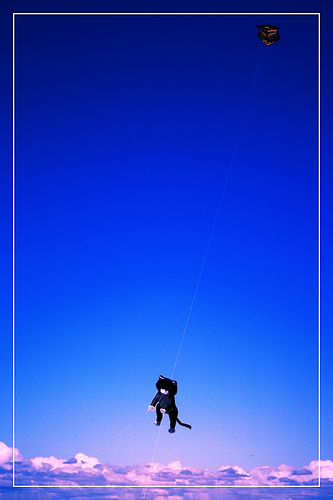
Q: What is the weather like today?
A: It is clear.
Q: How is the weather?
A: It is clear.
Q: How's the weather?
A: It is clear.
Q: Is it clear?
A: Yes, it is clear.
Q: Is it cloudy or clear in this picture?
A: It is clear.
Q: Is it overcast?
A: No, it is clear.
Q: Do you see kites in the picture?
A: Yes, there is a kite.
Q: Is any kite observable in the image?
A: Yes, there is a kite.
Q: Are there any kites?
A: Yes, there is a kite.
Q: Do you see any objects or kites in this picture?
A: Yes, there is a kite.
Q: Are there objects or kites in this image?
A: Yes, there is a kite.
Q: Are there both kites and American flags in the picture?
A: No, there is a kite but no American flags.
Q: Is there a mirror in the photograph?
A: No, there are no mirrors.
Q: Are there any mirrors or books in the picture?
A: No, there are no mirrors or books.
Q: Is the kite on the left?
A: No, the kite is on the right of the image.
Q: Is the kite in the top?
A: Yes, the kite is in the top of the image.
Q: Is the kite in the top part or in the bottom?
A: The kite is in the top of the image.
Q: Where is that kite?
A: The kite is in the sky.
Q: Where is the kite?
A: The kite is in the sky.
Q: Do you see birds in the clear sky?
A: No, there is a kite in the sky.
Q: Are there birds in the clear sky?
A: No, there is a kite in the sky.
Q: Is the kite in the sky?
A: Yes, the kite is in the sky.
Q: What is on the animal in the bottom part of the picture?
A: The kite is on the cat.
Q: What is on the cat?
A: The kite is on the cat.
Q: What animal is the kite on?
A: The kite is on the cat.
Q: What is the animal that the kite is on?
A: The animal is a cat.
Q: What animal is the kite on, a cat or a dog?
A: The kite is on a cat.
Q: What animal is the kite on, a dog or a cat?
A: The kite is on a cat.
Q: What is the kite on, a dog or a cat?
A: The kite is on a cat.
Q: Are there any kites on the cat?
A: Yes, there is a kite on the cat.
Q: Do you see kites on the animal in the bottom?
A: Yes, there is a kite on the cat.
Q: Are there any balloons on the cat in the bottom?
A: No, there is a kite on the cat.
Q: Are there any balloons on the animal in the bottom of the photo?
A: No, there is a kite on the cat.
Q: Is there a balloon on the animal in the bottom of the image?
A: No, there is a kite on the cat.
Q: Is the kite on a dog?
A: No, the kite is on the cat.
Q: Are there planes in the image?
A: No, there are no planes.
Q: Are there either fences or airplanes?
A: No, there are no airplanes or fences.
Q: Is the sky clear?
A: Yes, the sky is clear.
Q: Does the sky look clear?
A: Yes, the sky is clear.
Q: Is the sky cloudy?
A: No, the sky is clear.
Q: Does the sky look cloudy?
A: No, the sky is clear.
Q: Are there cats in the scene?
A: Yes, there is a cat.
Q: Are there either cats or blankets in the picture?
A: Yes, there is a cat.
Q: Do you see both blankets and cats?
A: No, there is a cat but no blankets.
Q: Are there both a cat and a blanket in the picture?
A: No, there is a cat but no blankets.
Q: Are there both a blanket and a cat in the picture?
A: No, there is a cat but no blankets.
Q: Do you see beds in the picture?
A: No, there are no beds.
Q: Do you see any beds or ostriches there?
A: No, there are no beds or ostriches.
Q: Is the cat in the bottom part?
A: Yes, the cat is in the bottom of the image.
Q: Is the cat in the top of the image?
A: No, the cat is in the bottom of the image.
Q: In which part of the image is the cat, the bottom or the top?
A: The cat is in the bottom of the image.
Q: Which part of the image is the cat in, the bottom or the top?
A: The cat is in the bottom of the image.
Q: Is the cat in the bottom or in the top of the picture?
A: The cat is in the bottom of the image.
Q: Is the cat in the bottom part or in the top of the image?
A: The cat is in the bottom of the image.